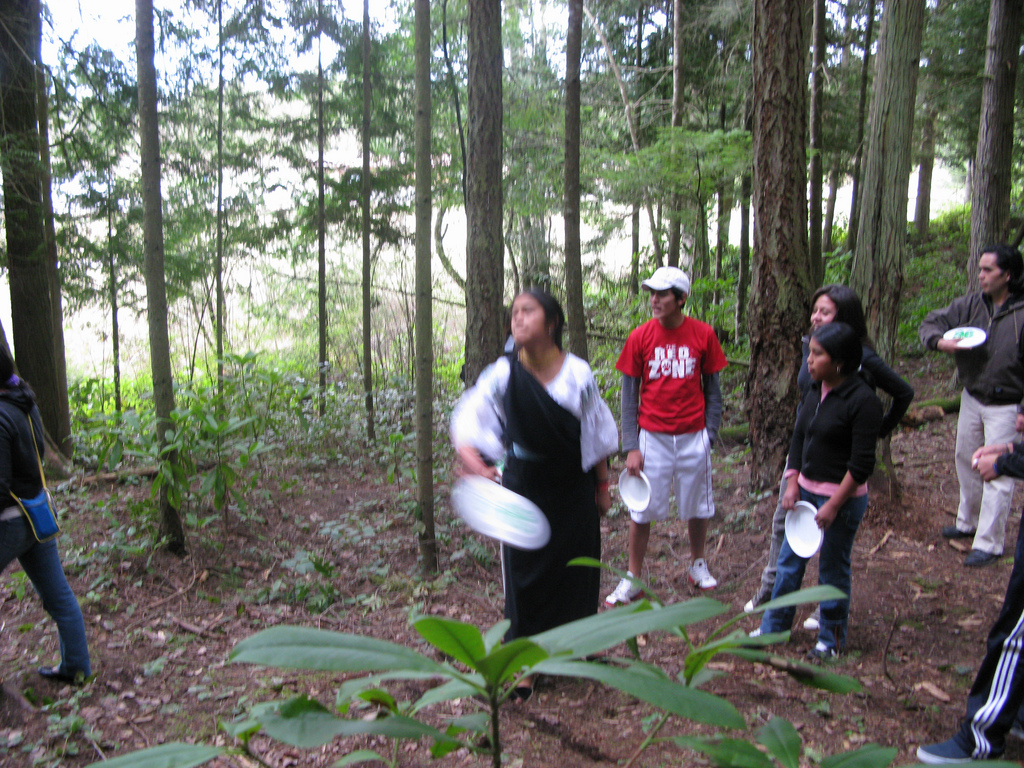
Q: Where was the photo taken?
A: Woods.